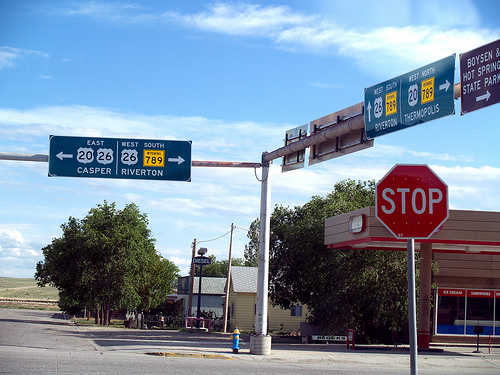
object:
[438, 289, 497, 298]
sign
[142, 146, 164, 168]
sign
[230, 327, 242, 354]
fire hydrant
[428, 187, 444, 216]
white letters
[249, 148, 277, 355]
of pole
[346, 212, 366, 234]
sign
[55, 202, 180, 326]
trees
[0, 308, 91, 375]
road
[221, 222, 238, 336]
telephone pole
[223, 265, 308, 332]
yellow house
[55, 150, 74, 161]
left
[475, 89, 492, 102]
arrow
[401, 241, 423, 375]
pole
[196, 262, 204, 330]
pole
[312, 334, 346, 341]
sign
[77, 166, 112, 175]
casper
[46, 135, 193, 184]
sign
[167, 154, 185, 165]
direction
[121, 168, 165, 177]
riverton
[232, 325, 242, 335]
yellow top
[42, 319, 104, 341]
street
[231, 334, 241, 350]
blue bottom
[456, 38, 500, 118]
sign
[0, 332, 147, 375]
intersection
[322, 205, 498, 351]
store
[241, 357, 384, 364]
curb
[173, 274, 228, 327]
blue house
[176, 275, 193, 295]
sign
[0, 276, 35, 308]
hill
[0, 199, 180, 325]
background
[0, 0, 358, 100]
sky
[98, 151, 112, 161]
numbers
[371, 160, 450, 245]
stop sign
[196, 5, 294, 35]
clouds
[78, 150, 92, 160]
number 20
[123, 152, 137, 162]
number 26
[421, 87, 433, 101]
number 789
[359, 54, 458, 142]
sign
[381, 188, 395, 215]
letter s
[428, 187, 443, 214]
letter p